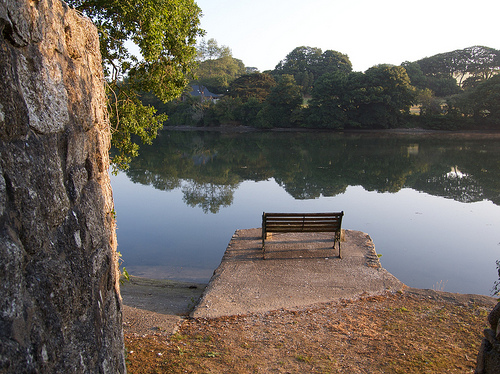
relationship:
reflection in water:
[110, 130, 499, 214] [109, 131, 499, 297]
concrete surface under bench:
[189, 229, 405, 319] [261, 212, 343, 259]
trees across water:
[136, 46, 499, 130] [109, 131, 499, 297]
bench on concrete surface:
[261, 212, 343, 259] [189, 229, 405, 319]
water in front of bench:
[109, 131, 499, 297] [261, 212, 343, 259]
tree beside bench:
[67, 0, 206, 170] [261, 212, 343, 259]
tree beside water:
[67, 0, 206, 170] [109, 131, 499, 297]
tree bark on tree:
[0, 0, 127, 374] [0, 0, 207, 374]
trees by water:
[136, 46, 499, 130] [109, 131, 499, 297]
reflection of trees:
[110, 130, 499, 214] [136, 46, 499, 130]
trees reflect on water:
[136, 46, 499, 130] [109, 131, 499, 297]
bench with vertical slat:
[261, 212, 343, 259] [300, 214, 306, 233]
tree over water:
[67, 0, 206, 170] [109, 131, 499, 297]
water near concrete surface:
[109, 131, 499, 297] [189, 229, 405, 319]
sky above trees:
[123, 1, 499, 70] [136, 46, 499, 130]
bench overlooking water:
[261, 212, 343, 259] [109, 131, 499, 297]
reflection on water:
[110, 130, 499, 214] [109, 131, 499, 297]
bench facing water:
[261, 212, 343, 259] [109, 131, 499, 297]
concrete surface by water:
[189, 229, 405, 319] [109, 131, 499, 297]